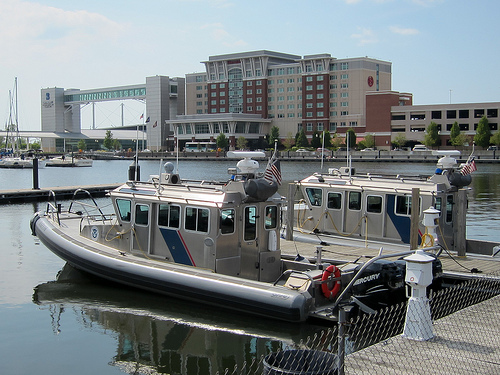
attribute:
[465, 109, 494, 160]
tree — short, green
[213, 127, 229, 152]
tree — short, green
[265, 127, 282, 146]
tree — short, green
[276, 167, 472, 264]
ship — big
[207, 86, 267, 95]
windows — glass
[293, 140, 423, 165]
parking lot — multi story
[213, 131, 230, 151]
tree — short, green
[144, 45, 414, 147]
building — in the picture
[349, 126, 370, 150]
tree — green, short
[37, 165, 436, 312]
ship — big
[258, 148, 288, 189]
flag — american 